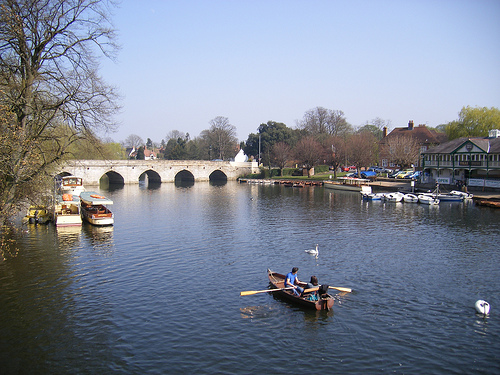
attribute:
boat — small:
[267, 268, 335, 311]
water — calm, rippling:
[0, 181, 499, 374]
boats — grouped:
[361, 185, 469, 204]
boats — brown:
[54, 194, 114, 226]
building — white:
[421, 139, 500, 193]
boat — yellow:
[22, 195, 53, 225]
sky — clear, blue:
[0, 0, 500, 145]